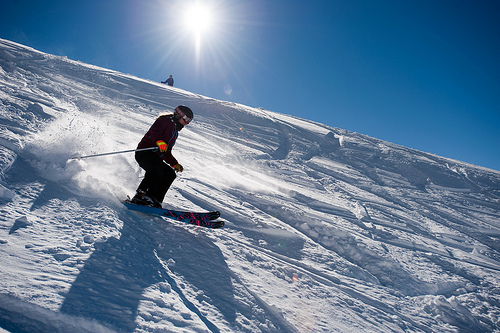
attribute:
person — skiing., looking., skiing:
[128, 108, 227, 235]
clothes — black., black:
[137, 123, 181, 208]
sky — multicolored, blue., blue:
[1, 0, 497, 173]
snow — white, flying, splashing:
[0, 37, 499, 331]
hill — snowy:
[3, 40, 499, 324]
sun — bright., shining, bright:
[137, 5, 251, 81]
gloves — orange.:
[157, 138, 186, 171]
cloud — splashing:
[13, 107, 133, 194]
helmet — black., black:
[169, 102, 198, 131]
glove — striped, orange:
[154, 135, 174, 156]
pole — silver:
[70, 139, 164, 160]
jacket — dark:
[139, 112, 184, 164]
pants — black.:
[133, 154, 178, 205]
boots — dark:
[133, 187, 162, 208]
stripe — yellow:
[156, 146, 169, 147]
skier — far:
[162, 72, 182, 89]